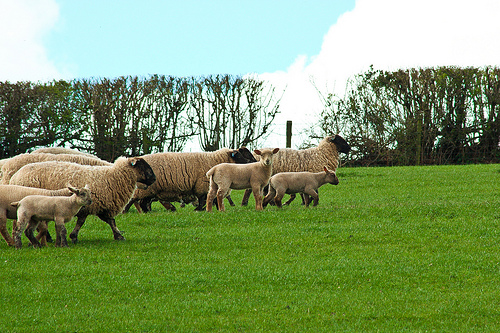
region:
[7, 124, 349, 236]
herd of sheep walking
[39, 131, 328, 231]
sheep are light brown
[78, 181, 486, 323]
grass is thick and green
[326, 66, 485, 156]
trees behind sheep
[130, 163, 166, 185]
sheep have black faces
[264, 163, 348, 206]
sheep is leaning forward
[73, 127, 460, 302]
sheep walking in grass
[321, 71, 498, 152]
trees are tall and thin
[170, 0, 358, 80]
sky is blue and cloudy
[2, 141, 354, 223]
sheep in a herd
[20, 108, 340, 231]
herd of sheep are walking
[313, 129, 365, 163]
sheep has black face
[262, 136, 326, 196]
sheep have brown fur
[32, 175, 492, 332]
grass is green and thick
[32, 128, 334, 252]
sheep walking on grass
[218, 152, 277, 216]
sheep looking at camera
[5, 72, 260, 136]
grove of trees behind sheep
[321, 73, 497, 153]
trees are tall and green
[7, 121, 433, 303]
sheep walking along hill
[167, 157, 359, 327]
the grass is green and clear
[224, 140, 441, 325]
the grass is green and clear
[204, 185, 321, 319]
the grass is green and clear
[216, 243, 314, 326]
the grass is green and clear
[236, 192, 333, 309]
the green is green and visible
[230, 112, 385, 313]
the green is green and visible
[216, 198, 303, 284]
the green is green and visible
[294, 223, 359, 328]
the green is green and visible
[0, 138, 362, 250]
herd of sheep in field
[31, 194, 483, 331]
short green grass on field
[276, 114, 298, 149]
pole between trees in distance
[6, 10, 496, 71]
somewhat cloudy blue sky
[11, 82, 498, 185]
tree line with top chopped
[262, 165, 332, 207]
Baby sheep at the front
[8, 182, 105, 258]
Baby sheep in the rear of the heard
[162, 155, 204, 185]
Thick tan colored wool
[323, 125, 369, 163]
Black face of adult sheep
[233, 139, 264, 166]
Black face of adult sheep